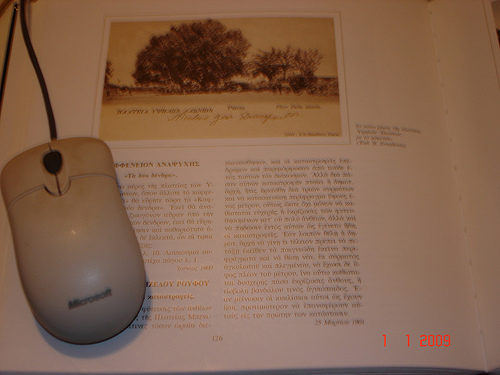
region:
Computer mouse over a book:
[0, 0, 150, 350]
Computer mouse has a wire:
[0, 0, 165, 355]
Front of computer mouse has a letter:
[50, 275, 120, 325]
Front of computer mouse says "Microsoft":
[58, 282, 125, 316]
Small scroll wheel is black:
[30, 145, 60, 170]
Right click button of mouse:
[0, 131, 51, 201]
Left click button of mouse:
[48, 134, 118, 189]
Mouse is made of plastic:
[0, 113, 156, 349]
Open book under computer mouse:
[10, 3, 497, 373]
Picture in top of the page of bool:
[81, 10, 361, 157]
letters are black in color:
[178, 174, 389, 291]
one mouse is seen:
[12, 138, 157, 343]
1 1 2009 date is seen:
[367, 321, 462, 371]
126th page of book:
[90, 25, 410, 350]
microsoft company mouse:
[40, 266, 140, 326]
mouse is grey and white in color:
[16, 136, 164, 321]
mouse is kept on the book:
[15, 131, 212, 311]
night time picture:
[39, 38, 421, 330]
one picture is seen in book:
[98, 36, 345, 141]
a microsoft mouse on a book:
[0, 136, 147, 346]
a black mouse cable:
[17, 0, 57, 138]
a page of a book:
[0, 0, 497, 370]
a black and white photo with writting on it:
[95, 14, 342, 139]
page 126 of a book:
[211, 332, 223, 341]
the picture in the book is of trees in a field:
[102, 16, 339, 101]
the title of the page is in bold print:
[114, 157, 201, 169]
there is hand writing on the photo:
[167, 109, 299, 126]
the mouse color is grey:
[0, 136, 146, 346]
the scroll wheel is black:
[42, 150, 63, 173]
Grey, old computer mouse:
[0, 135, 147, 345]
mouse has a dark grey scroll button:
[41, 149, 63, 172]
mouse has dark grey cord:
[18, 0, 58, 140]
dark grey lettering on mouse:
[66, 286, 113, 311]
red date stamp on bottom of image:
[381, 332, 451, 349]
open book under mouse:
[0, 0, 499, 373]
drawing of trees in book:
[100, 16, 339, 138]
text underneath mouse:
[112, 156, 364, 328]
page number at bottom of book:
[211, 333, 224, 341]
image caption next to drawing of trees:
[354, 122, 424, 149]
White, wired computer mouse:
[0, 121, 147, 344]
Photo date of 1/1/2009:
[381, 332, 451, 349]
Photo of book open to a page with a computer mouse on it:
[2, 2, 499, 369]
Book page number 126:
[211, 332, 226, 342]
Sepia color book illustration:
[98, 17, 344, 138]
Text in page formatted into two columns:
[116, 157, 366, 328]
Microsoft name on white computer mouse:
[66, 286, 113, 313]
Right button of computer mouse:
[48, 135, 116, 194]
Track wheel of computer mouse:
[43, 150, 63, 175]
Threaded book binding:
[419, 0, 490, 330]